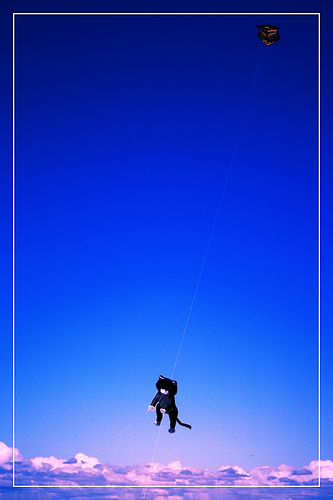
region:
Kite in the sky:
[249, 20, 284, 51]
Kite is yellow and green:
[252, 18, 282, 51]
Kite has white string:
[161, 18, 284, 376]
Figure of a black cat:
[136, 371, 197, 437]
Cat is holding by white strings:
[79, 348, 217, 472]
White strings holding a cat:
[36, 406, 184, 493]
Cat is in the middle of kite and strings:
[3, 0, 331, 498]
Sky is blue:
[6, 0, 328, 460]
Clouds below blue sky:
[1, 456, 330, 496]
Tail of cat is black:
[173, 413, 196, 432]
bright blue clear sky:
[48, 162, 167, 333]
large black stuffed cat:
[147, 370, 192, 434]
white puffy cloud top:
[67, 452, 102, 470]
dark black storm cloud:
[15, 478, 55, 495]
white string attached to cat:
[171, 257, 211, 385]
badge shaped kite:
[254, 19, 283, 50]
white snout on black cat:
[158, 386, 168, 395]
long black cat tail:
[174, 412, 194, 430]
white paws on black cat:
[149, 403, 168, 414]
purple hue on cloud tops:
[132, 472, 182, 494]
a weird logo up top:
[256, 23, 304, 69]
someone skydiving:
[142, 345, 236, 486]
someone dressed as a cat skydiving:
[136, 367, 216, 434]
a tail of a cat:
[170, 416, 193, 432]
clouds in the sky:
[43, 458, 170, 498]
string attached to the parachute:
[171, 209, 239, 331]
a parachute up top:
[245, 21, 293, 57]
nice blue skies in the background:
[61, 285, 172, 341]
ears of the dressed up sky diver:
[155, 372, 184, 381]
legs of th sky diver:
[152, 416, 190, 450]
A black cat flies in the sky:
[132, 367, 220, 447]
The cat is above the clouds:
[11, 367, 328, 495]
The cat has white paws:
[128, 363, 199, 439]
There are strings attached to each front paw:
[122, 393, 179, 495]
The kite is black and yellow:
[221, 11, 295, 75]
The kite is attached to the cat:
[157, 20, 314, 434]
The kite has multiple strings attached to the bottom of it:
[235, 15, 304, 115]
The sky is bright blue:
[19, 122, 322, 445]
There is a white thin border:
[16, 302, 325, 493]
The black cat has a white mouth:
[129, 367, 213, 441]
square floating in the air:
[246, 16, 295, 61]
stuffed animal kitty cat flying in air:
[133, 359, 209, 447]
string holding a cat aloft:
[163, 305, 224, 347]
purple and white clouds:
[18, 443, 116, 481]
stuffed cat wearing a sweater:
[134, 376, 198, 438]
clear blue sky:
[41, 35, 151, 104]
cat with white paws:
[131, 357, 217, 448]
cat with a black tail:
[110, 348, 210, 445]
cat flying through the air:
[131, 350, 217, 456]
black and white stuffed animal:
[121, 340, 230, 444]